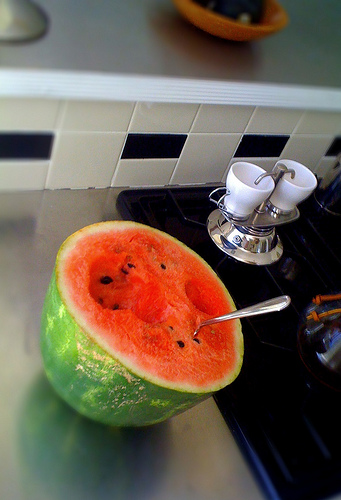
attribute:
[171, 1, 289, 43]
bowl — orange, half, wood, brown, wooden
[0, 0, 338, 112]
counter — metal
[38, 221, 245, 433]
watermelon — juicy, in half, red, green, halved, large, pink in center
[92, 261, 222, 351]
seeds — black, small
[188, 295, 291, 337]
spoon — silver, steel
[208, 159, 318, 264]
espressor — silver, small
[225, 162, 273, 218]
cup — white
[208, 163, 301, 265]
machine — metal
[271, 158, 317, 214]
cup — white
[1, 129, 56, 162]
tile — black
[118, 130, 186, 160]
tile — black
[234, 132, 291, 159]
tile — black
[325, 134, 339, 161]
tile — black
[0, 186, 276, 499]
counter — stainless steel, steel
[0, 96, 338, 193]
tiles — black, ceramic, white, tan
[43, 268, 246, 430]
rind — green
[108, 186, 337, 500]
tray — black